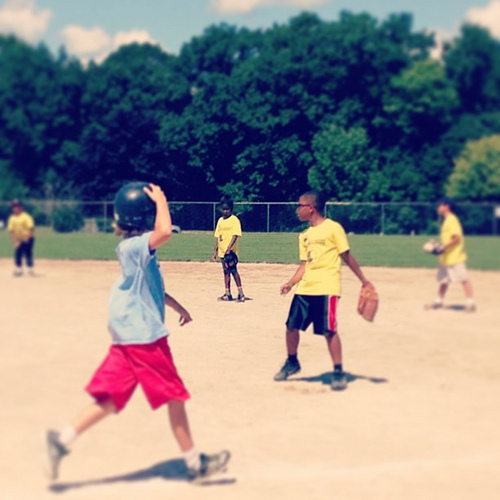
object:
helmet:
[111, 179, 157, 228]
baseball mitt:
[356, 281, 381, 320]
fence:
[0, 194, 498, 234]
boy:
[272, 186, 381, 392]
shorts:
[280, 289, 337, 337]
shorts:
[83, 336, 191, 416]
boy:
[42, 171, 231, 483]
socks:
[187, 447, 229, 480]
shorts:
[219, 246, 237, 276]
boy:
[209, 196, 246, 303]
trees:
[442, 132, 499, 240]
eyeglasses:
[294, 201, 312, 211]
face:
[295, 191, 307, 221]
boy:
[421, 199, 474, 314]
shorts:
[435, 260, 467, 282]